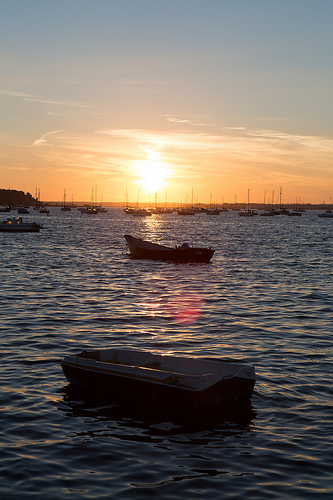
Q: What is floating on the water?
A: Boats.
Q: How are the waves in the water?
A: Small.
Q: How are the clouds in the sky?
A: Few and light.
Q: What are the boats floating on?
A: Water.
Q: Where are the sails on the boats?
A: Down.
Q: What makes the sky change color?
A: Light and clouds.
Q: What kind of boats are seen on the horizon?
A: Sailboats.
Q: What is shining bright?
A: The sun.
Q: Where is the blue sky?
A: At top of photo.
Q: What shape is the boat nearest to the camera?
A: Rectangle.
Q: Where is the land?
A: In background on left.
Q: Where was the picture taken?
A: At the water.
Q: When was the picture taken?
A: Sunset.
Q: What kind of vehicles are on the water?
A: Boats.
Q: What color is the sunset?
A: Orange.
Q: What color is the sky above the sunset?
A: Blue.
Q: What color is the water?
A: Blue.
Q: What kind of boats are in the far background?
A: Sailboats.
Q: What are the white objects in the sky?
A: Clouds.